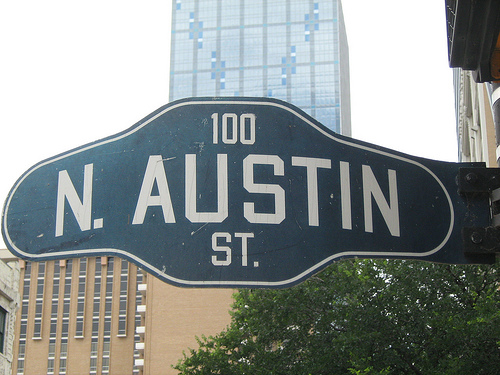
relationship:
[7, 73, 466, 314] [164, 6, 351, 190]
sign by skyscraper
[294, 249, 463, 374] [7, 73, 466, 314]
tree by sign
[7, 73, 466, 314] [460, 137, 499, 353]
sign on post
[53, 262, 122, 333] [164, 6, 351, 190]
window on skyscraper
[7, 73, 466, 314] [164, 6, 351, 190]
sign on skyscraper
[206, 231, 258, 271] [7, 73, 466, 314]
abbreviation on sign